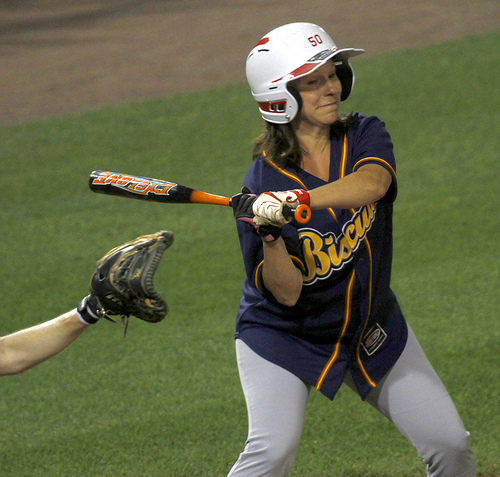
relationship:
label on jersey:
[361, 318, 388, 355] [231, 109, 412, 409]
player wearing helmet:
[221, 22, 479, 476] [241, 22, 360, 123]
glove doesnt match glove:
[253, 186, 308, 221] [229, 185, 259, 215]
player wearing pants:
[221, 11, 471, 474] [219, 323, 469, 475]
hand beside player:
[78, 228, 172, 324] [221, 22, 479, 476]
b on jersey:
[296, 223, 333, 283] [233, 114, 409, 402]